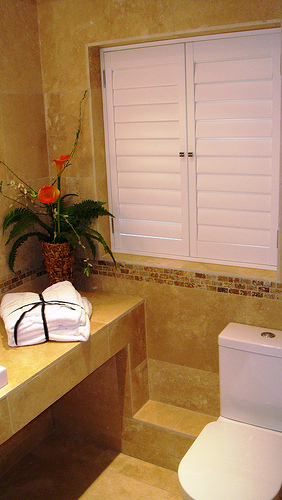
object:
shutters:
[103, 42, 191, 257]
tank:
[218, 320, 282, 432]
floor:
[0, 427, 187, 499]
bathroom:
[0, 0, 282, 498]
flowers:
[37, 184, 60, 203]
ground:
[220, 78, 256, 118]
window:
[102, 32, 281, 272]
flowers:
[51, 153, 72, 177]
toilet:
[177, 321, 282, 499]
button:
[260, 331, 276, 340]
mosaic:
[0, 255, 282, 313]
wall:
[0, 2, 282, 471]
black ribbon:
[4, 292, 90, 347]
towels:
[0, 280, 93, 347]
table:
[0, 281, 150, 443]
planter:
[40, 240, 76, 287]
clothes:
[0, 280, 93, 347]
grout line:
[106, 324, 111, 359]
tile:
[126, 300, 147, 372]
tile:
[5, 323, 110, 433]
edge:
[217, 321, 227, 419]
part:
[83, 332, 92, 344]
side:
[78, 261, 273, 421]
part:
[174, 422, 230, 495]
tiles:
[110, 437, 141, 484]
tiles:
[99, 253, 272, 310]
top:
[217, 321, 282, 355]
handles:
[179, 151, 185, 158]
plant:
[0, 86, 117, 280]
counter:
[0, 285, 144, 405]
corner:
[20, 0, 76, 181]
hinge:
[102, 68, 106, 89]